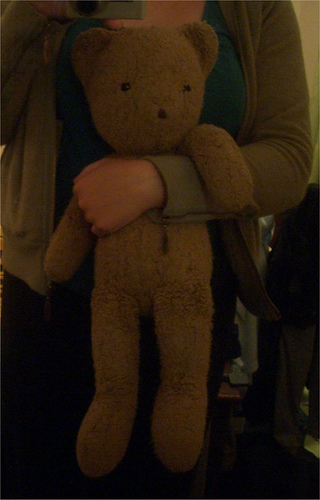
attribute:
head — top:
[102, 34, 202, 79]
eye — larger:
[119, 80, 130, 91]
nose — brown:
[150, 101, 174, 130]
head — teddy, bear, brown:
[66, 20, 216, 153]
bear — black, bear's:
[43, 21, 253, 478]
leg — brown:
[75, 286, 140, 478]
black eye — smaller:
[183, 83, 192, 91]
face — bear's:
[92, 42, 201, 176]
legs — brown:
[58, 284, 211, 480]